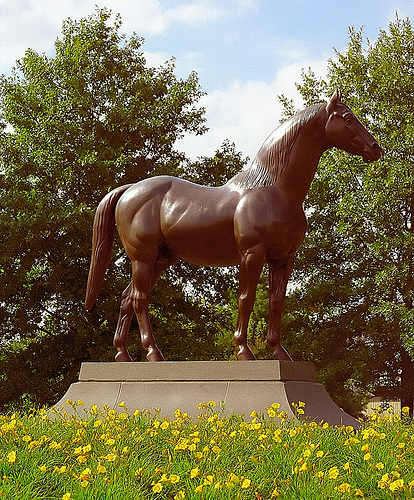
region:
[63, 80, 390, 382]
brown statue of horse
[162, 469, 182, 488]
small yellow flower in field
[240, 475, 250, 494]
small yellow flower in field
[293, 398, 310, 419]
small yellow flower in field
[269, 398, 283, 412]
small yellow flower in field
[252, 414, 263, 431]
small yellow flower in field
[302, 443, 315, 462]
small yellow flower in field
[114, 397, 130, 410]
small yellow flower in field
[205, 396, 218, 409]
small yellow flower in field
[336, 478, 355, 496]
small yellow flower in field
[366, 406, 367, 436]
part of yellow flower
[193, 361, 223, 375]
bottom of a sculpture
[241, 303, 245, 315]
front leg of a horse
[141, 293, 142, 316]
back leg of a horse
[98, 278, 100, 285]
tail of a horse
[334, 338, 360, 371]
leaves of a tree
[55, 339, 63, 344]
part of a tall tree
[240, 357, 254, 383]
part of a brick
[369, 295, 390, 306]
branches of a tree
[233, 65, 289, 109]
part of the sky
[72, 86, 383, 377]
statue of horse on base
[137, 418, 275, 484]
yellow flowers in grass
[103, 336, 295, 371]
horse hooves on statue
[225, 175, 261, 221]
light reflection on statue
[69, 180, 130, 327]
tail on horse statue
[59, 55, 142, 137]
green leaves on trees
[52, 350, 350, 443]
cement base under statue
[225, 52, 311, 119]
white clouds in daytime sky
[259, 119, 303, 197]
mane on neck of horse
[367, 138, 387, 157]
nostril on horse nose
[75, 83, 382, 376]
The horse is brown.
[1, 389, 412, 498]
The flowers are yellow.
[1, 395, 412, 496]
The grass is green.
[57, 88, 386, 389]
Sculpture of a horse.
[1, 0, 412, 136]
The sky is blue.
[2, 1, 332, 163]
The clouds are white.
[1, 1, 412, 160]
The sky is partly cloudy.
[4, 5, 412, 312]
The trees are green.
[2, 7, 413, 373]
The trees are leafy.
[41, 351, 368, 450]
The stand is concrete.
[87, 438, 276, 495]
Yellow flowers sticking out of the grass.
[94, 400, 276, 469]
Long green grass near yellow flowers.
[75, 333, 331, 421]
Horse is standing on concrete platform.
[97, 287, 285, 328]
Horse has brown legs.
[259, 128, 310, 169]
Horse has dark mane.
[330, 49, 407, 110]
Green leaves on trees.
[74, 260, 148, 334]
Horse has brown tail.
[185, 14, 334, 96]
Sky is blue with white clouds.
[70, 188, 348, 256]
Horse is brown standing on concrete.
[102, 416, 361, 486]
Green grass has yellow flowers.